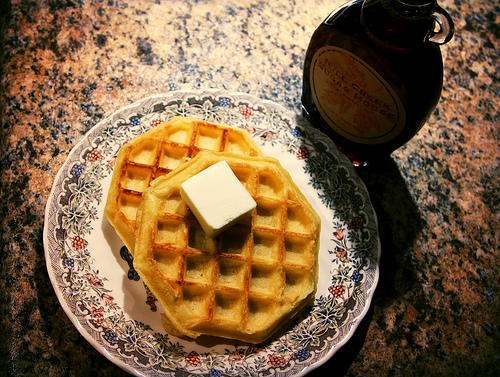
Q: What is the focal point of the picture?
A: Waffles.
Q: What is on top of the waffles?
A: Butter.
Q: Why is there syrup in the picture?
A: Pour on waffles.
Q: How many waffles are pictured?
A: Two.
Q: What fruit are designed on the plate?
A: Red and black berries.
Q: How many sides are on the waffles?
A: Eight.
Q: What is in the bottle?
A: Maple syrup.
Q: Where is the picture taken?
A: Counter.